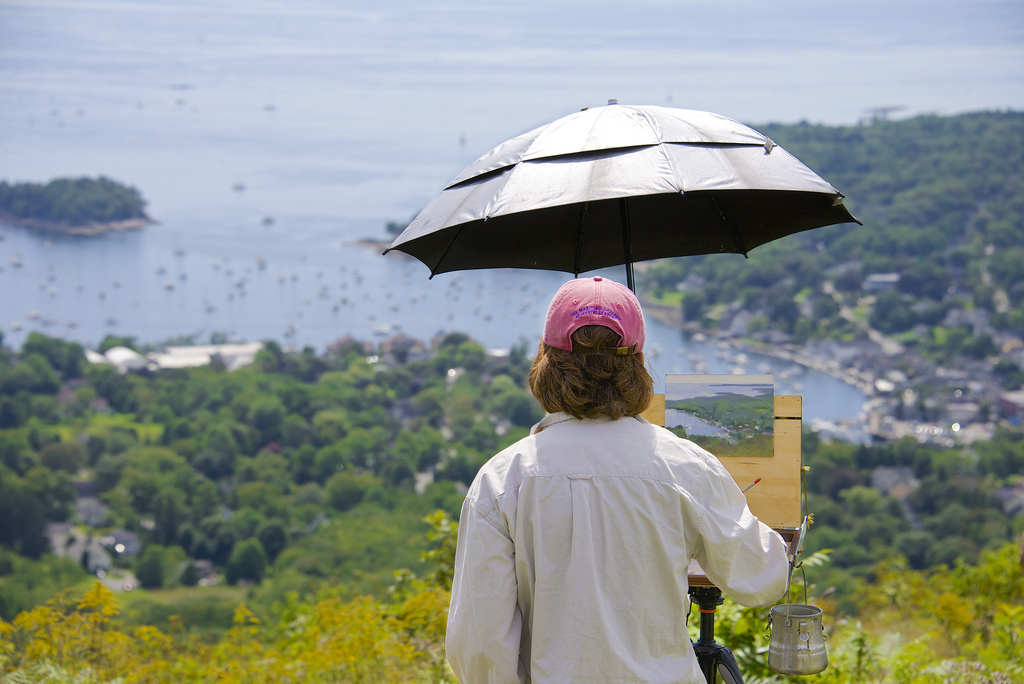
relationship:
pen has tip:
[732, 476, 761, 499] [754, 476, 761, 499]